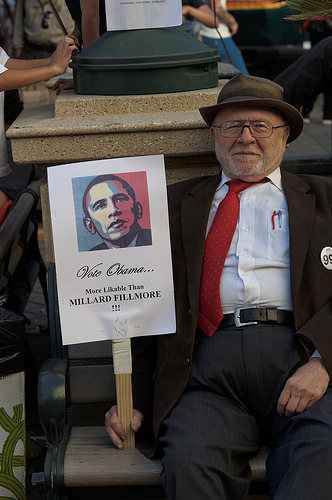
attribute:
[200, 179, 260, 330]
tie — red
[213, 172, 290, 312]
dress shirt — white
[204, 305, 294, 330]
belt — black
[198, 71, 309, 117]
hat — dark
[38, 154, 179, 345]
poster — white, square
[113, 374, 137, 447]
handle — brown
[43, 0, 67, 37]
strap — black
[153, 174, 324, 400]
jacket — brown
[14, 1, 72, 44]
shirt — long sleeve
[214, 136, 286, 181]
beard — gray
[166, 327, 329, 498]
pants — dark